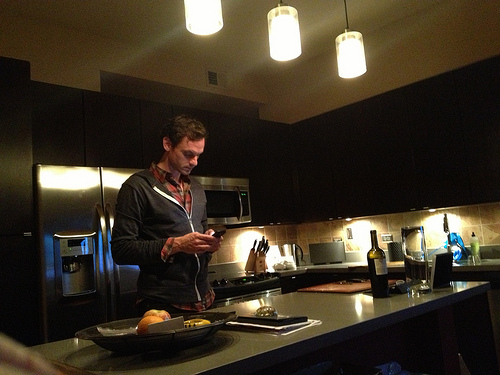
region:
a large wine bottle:
[364, 220, 393, 301]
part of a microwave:
[181, 173, 255, 228]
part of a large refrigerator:
[43, 160, 160, 338]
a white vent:
[203, 63, 238, 91]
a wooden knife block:
[246, 245, 270, 272]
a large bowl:
[67, 304, 234, 347]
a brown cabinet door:
[83, 87, 143, 169]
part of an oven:
[206, 259, 281, 307]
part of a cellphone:
[208, 225, 230, 238]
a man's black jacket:
[108, 166, 220, 308]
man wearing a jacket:
[111, 106, 222, 302]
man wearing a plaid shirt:
[105, 105, 230, 301]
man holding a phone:
[90, 92, 227, 307]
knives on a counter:
[245, 226, 276, 274]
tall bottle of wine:
[360, 220, 393, 313]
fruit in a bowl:
[125, 305, 157, 337]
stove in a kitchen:
[227, 270, 282, 290]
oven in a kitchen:
[220, 161, 260, 231]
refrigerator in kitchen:
[37, 156, 107, 316]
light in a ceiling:
[315, 10, 380, 90]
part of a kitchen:
[388, 170, 411, 191]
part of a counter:
[351, 302, 366, 314]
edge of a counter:
[363, 296, 378, 334]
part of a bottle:
[381, 280, 392, 287]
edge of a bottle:
[375, 273, 378, 285]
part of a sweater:
[168, 228, 175, 244]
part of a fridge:
[68, 188, 88, 221]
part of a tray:
[154, 337, 161, 348]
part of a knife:
[265, 255, 267, 267]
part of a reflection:
[56, 198, 73, 228]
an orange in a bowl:
[137, 315, 162, 331]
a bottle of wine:
[366, 230, 388, 298]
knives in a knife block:
[251, 236, 268, 275]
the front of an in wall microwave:
[205, 177, 249, 222]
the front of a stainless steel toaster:
[309, 244, 344, 265]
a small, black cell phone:
[211, 226, 224, 245]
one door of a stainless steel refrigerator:
[35, 165, 103, 327]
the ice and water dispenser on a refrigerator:
[55, 235, 98, 294]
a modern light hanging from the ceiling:
[269, 5, 301, 62]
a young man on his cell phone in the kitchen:
[110, 115, 220, 308]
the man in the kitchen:
[84, 105, 225, 308]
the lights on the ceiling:
[176, 0, 382, 91]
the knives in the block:
[244, 236, 278, 274]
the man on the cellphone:
[101, 103, 239, 305]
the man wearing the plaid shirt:
[120, 101, 239, 320]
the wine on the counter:
[361, 225, 408, 303]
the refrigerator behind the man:
[27, 158, 143, 327]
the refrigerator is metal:
[26, 150, 132, 318]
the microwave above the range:
[193, 171, 249, 227]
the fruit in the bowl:
[135, 300, 165, 337]